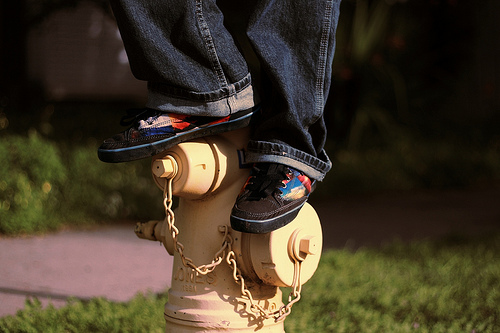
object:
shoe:
[97, 109, 255, 162]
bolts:
[148, 141, 240, 200]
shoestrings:
[264, 163, 283, 195]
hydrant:
[136, 123, 322, 333]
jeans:
[114, 0, 341, 181]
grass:
[0, 106, 499, 237]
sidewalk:
[0, 198, 499, 315]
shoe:
[230, 160, 317, 233]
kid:
[100, 0, 343, 234]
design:
[138, 112, 197, 136]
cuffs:
[145, 73, 253, 116]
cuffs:
[240, 139, 333, 182]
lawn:
[1, 222, 500, 333]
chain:
[162, 179, 227, 276]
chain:
[223, 228, 303, 322]